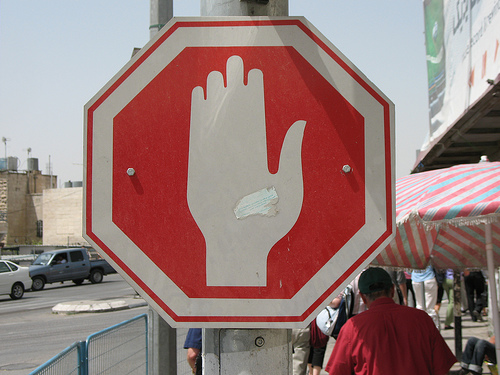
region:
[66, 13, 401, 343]
Red and white sign.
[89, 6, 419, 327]
Sign with hand on it.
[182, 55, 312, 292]
Large white hand on red background.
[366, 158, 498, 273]
Pink, blue and white umbrella.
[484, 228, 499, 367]
Long white umbrella pole.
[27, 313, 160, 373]
Two sections on a blue gate.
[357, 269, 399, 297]
Dark hat worn by a man.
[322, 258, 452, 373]
Man in red shirt.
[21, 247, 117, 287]
Grey trunk in street.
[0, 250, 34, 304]
White car in street.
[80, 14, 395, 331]
stop sign with not letters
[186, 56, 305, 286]
a hand that means stop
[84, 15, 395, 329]
a shape that means stop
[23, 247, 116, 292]
a pick-up pulling away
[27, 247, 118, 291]
a pick-up backing up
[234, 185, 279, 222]
a mark on the palm of the hand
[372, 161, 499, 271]
a canopy with pink stripes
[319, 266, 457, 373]
a man in a short sleeve red shirt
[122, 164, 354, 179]
two heads of nails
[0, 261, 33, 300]
a white car parked on the street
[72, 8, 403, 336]
Red and white stop sign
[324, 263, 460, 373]
a man wearing a red shirt and hat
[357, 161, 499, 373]
A pink and blue striped umbrella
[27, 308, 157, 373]
a blue fence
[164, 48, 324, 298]
a white hand on a sign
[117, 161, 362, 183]
two bolts on a sign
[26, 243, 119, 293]
a parked blue truck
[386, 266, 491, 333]
a crowd of people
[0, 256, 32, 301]
a white parked car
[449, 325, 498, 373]
a person sitting on the curb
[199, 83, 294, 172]
the hand is white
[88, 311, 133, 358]
the gate is blue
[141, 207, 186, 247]
the sign is red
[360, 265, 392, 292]
the hat is green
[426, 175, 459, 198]
the umbrella is stripped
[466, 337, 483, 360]
the pants are black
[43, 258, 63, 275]
the truck is gray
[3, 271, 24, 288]
the car is white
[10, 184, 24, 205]
the building is brown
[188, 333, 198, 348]
the shirt is blue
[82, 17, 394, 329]
Red and white traffic sign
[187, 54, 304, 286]
White hand on traffic sign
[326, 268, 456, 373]
Man walking under red and white umbrella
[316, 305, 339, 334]
White shirt worn by man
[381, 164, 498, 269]
Pink, aqua, and yellow canopy of the umbrella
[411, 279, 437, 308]
Woman wearing white pants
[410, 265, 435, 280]
Woman wearing a aqua color top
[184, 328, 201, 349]
Blue sleeve of man standing behind the wall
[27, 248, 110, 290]
Blue pickup truck in traffic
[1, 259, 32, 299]
Back end of the white car